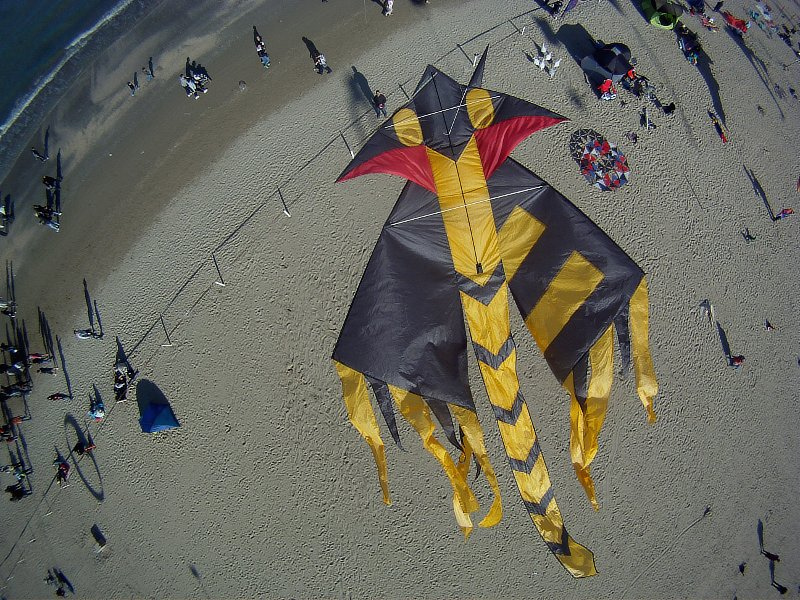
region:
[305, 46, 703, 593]
a large kite with eyes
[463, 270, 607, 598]
a long yellow and gray tail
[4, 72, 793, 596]
several people standing on the beach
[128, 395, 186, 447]
a blue umbrella on the beach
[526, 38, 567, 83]
five white birds on the beach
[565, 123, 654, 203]
a red white and blue kite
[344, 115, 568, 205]
two red areas on the large kite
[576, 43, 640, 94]
a tent with two people in red in front of it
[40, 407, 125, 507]
a shadow of a circle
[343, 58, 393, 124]
a long shadow from the man flying the kite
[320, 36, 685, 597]
kite flying in air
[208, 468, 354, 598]
sand on the beach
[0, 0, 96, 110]
water at the beach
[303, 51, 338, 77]
person walking on beach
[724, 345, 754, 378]
person walking on sand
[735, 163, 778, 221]
shadow of person on beach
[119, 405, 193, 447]
blue umbrella on the beach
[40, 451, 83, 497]
person standing on beach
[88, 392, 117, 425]
person standing on beach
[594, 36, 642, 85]
black umbrella on beach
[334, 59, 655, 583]
A black and yellow kite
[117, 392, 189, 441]
A blue tent on the beach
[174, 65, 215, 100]
A group of people walk on the beach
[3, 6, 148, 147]
The blue ocean next to the beach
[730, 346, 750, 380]
A person walks on the beach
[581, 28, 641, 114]
A black tent on the beach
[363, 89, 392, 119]
A man looks upwards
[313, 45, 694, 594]
kite is black, yellow and red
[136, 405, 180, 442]
umbrella in the sand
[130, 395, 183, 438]
umbrella in sand is blue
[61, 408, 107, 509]
shadow in the sand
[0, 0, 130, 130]
small waves rolling in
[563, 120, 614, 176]
multi colored umbrella in sand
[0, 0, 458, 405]
sand near water is wet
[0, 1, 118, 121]
most of water is calm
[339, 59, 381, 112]
shadow of man in sand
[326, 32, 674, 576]
kite in the sky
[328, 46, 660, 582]
Large black, yellow and red kite in the air.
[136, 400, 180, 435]
Blue umbrella in the sand.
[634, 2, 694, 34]
Green tent in the upper left.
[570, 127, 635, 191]
Colorful kite below the big kite to the right.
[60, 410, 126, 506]
Shadow circle on the sand to the left.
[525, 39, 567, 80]
Group of six white birds to the left.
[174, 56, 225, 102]
Two people pushing a stroller near the water.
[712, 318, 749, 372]
Man in a red shirt and his shadow to the right.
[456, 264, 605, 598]
Long black and yellow tail of the kite.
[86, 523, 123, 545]
Square shadow below a circle one.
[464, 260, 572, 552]
stripes on the kite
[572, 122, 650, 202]
umbrellas are below kite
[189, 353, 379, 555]
sand is on the beach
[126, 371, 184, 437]
the umbrella is blue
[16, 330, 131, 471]
people on the beach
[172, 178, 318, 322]
poles in the sand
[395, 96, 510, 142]
the eyes are golden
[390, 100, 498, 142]
golden eyes on the kite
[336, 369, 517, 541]
streamers on the kite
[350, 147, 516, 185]
the strip of red is on the kite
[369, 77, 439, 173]
kite has yellow eyes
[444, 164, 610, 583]
kite has yellow tail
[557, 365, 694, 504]
kite has yellow frill